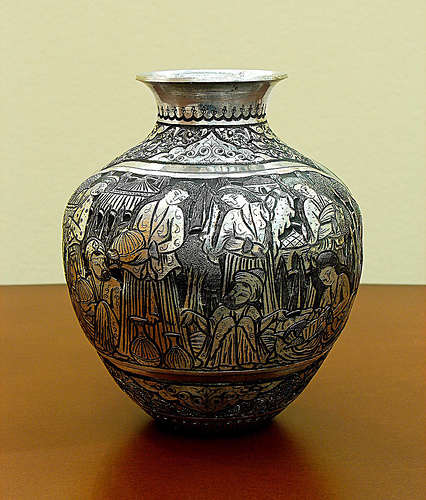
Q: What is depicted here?
A: Vase.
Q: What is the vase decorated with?
A: Market scene.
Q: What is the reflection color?
A: Red.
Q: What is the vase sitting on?
A: Table.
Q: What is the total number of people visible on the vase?
A: 7.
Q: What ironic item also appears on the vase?
A: Vases.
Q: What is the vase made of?
A: Metal.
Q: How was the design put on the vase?
A: Etched.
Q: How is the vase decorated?
A: With engravings of people.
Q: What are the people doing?
A: Sitting and standing.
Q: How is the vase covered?
A: With engravings.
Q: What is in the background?
A: A white wall.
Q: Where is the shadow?
A: Under the vase.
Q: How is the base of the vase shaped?
A: It is tapered.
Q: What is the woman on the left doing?
A: Holding a pot.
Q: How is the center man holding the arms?
A: Outstretched.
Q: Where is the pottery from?
A: Asia.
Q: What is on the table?
A: A vase.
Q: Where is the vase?
A: On the table.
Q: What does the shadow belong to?
A: The vase.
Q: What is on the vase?
A: Asian inscription.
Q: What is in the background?
A: A white wall.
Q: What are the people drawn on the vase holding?
A: Pottery.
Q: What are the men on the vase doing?
A: Sitting.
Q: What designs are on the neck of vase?
A: Swirls.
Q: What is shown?
A: A vase.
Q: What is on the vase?
A: People.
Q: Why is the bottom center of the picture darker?
A: It is shadow.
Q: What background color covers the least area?
A: Brown.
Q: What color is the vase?
A: Gray and white.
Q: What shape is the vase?
A: Round.